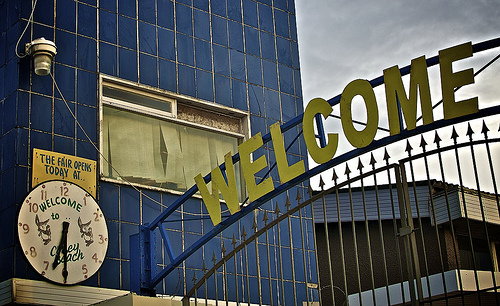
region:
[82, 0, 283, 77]
a blue tile building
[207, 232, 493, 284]
a iron gate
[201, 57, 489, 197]
yellow letters on gate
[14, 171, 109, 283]
a white round clock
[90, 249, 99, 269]
numbers on the clock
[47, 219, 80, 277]
hands on a clock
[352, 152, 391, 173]
arrows on the gate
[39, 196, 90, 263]
writting on the clock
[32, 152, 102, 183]
yellow and green sign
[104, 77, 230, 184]
a closed window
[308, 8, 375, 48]
this is the sky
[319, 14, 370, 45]
the sky is blue in color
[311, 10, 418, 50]
the sky is full of clouds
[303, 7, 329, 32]
the clouds are white in color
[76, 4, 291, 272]
this is a building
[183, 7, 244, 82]
the wall is made of tiles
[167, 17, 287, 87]
the wall is blue in color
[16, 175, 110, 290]
this is a clock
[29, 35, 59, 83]
this is a bulb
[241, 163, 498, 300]
this is a gate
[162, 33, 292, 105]
Blue tile on side of building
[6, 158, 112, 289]
Clock on side of building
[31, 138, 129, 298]
The clock tells customers what time the fair opens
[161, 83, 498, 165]
Welcome sign in front of the park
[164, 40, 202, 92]
Grout in between the tiles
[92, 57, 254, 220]
Window on side of building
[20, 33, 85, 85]
Light hanging on the wall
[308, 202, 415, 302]
The gate is metal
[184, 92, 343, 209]
The sign is yellow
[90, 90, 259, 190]
The window has blinds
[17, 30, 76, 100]
white light on side of building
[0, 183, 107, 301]
white gold and green clock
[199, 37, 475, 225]
gold letters that spell welcome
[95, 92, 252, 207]
window on side of building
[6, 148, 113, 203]
yellow and blue sign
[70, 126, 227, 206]
blinds in a window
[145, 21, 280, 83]
blue tile on building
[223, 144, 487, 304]
fence with sharp points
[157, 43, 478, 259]
blue metal frame holding gold letters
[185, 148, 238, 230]
a gold letter w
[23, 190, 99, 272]
white face of the clock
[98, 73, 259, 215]
closed window on a blue building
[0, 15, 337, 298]
a blue tiled building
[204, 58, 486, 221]
yellow lettering spelling out Welcome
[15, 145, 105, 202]
yellow sign with blue lettering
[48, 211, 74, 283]
black hands of the clock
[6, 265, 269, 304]
white trim on the blue building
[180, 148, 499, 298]
speared posts of the gate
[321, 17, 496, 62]
cloudy grey skies over the scene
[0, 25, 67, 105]
light attached to the side of the blue building